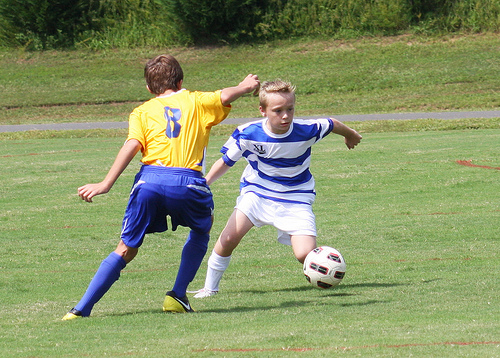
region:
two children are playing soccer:
[63, 54, 361, 319]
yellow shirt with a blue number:
[124, 88, 231, 168]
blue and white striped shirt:
[221, 119, 332, 203]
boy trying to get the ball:
[63, 53, 258, 317]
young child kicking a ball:
[196, 77, 363, 298]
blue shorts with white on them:
[120, 165, 213, 248]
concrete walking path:
[0, 113, 496, 134]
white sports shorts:
[233, 189, 316, 244]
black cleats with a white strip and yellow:
[161, 292, 192, 313]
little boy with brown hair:
[62, 54, 259, 318]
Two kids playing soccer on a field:
[62, 53, 363, 322]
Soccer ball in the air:
[299, 245, 348, 293]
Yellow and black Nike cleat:
[161, 288, 194, 315]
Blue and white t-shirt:
[218, 116, 335, 204]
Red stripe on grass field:
[176, 328, 497, 356]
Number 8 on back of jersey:
[156, 101, 187, 142]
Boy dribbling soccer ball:
[190, 75, 370, 297]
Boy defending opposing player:
[60, 59, 385, 317]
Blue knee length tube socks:
[70, 251, 203, 315]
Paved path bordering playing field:
[1, 101, 498, 140]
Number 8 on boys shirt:
[156, 103, 189, 138]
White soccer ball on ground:
[300, 246, 346, 292]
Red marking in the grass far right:
[445, 153, 498, 176]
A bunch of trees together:
[0, 0, 498, 42]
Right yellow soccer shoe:
[161, 290, 198, 318]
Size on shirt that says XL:
[251, 139, 265, 159]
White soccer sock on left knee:
[203, 248, 231, 289]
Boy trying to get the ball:
[202, 65, 360, 301]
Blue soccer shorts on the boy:
[119, 164, 214, 245]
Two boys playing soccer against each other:
[63, 54, 361, 319]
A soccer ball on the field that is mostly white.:
[301, 244, 346, 289]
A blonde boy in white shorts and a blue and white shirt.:
[193, 79, 360, 300]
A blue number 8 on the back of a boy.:
[162, 106, 182, 140]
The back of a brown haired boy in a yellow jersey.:
[62, 53, 261, 320]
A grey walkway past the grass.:
[0, 106, 499, 133]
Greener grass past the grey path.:
[2, 42, 499, 107]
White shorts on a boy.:
[231, 191, 318, 246]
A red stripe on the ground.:
[455, 157, 499, 172]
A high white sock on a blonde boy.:
[200, 250, 231, 295]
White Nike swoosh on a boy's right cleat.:
[171, 295, 192, 311]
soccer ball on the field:
[296, 228, 351, 293]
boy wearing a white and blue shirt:
[225, 115, 328, 216]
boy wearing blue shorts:
[96, 144, 217, 256]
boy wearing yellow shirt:
[108, 82, 223, 171]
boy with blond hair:
[253, 68, 313, 125]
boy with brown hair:
[138, 47, 193, 97]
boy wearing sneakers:
[155, 283, 197, 320]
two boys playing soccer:
[32, 28, 394, 319]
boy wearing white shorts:
[216, 176, 322, 253]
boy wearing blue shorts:
[101, 163, 222, 273]